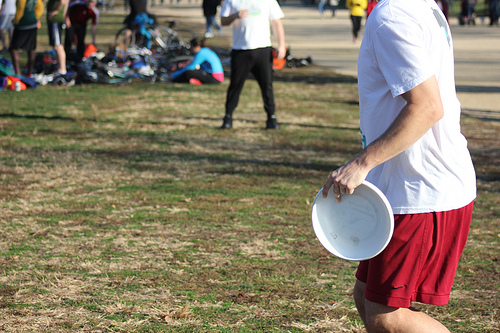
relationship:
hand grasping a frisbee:
[316, 149, 377, 199] [302, 180, 402, 275]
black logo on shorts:
[392, 282, 408, 290] [354, 198, 476, 308]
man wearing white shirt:
[318, 0, 478, 333] [356, 0, 478, 215]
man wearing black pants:
[318, 0, 478, 333] [183, 36, 292, 142]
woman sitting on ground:
[171, 38, 223, 90] [159, 83, 210, 128]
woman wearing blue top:
[171, 38, 223, 90] [194, 42, 220, 68]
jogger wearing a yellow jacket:
[344, 4, 363, 35] [357, 0, 359, 15]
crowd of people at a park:
[16, 2, 232, 90] [92, 93, 234, 218]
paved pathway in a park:
[302, 27, 370, 84] [92, 93, 234, 218]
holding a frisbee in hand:
[302, 180, 402, 275] [316, 149, 377, 199]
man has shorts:
[338, 16, 458, 118] [354, 198, 476, 308]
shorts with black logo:
[382, 219, 445, 282] [392, 285, 407, 290]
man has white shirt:
[338, 16, 458, 118] [367, 45, 427, 81]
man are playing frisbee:
[338, 16, 458, 118] [302, 180, 402, 275]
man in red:
[338, 16, 458, 118] [399, 226, 467, 279]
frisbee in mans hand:
[302, 180, 402, 275] [321, 162, 371, 204]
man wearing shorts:
[338, 16, 458, 118] [354, 198, 476, 308]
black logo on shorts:
[392, 285, 407, 290] [354, 198, 476, 308]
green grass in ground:
[140, 146, 253, 283] [0, 14, 500, 333]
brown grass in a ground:
[286, 138, 336, 151] [0, 14, 500, 333]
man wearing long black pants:
[338, 16, 458, 118] [183, 36, 292, 142]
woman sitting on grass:
[171, 38, 223, 90] [64, 99, 173, 135]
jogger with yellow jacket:
[344, 0, 368, 43] [346, 0, 377, 17]